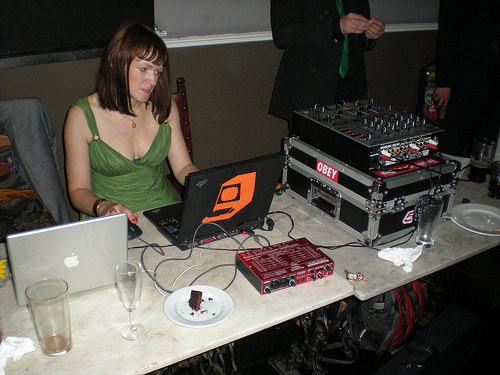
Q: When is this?
A: Nighttime.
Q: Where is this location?
A: Party.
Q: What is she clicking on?
A: Computer.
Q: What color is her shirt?
A: Green.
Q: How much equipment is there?
A: Plenty.